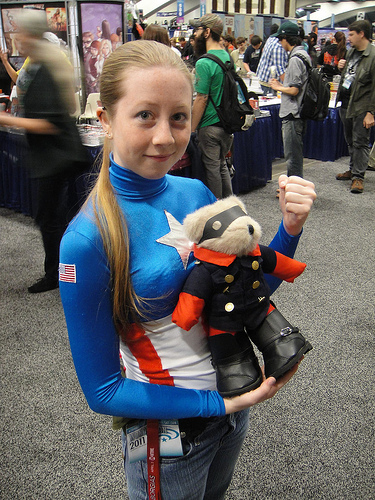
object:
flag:
[58, 262, 76, 283]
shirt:
[55, 151, 304, 417]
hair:
[79, 39, 194, 346]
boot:
[202, 329, 264, 398]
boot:
[246, 307, 313, 381]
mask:
[198, 204, 247, 244]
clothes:
[171, 242, 312, 398]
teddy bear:
[170, 193, 314, 399]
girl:
[59, 38, 317, 500]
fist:
[278, 174, 316, 228]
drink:
[270, 65, 277, 77]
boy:
[269, 21, 309, 198]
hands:
[268, 78, 277, 91]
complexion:
[120, 82, 160, 167]